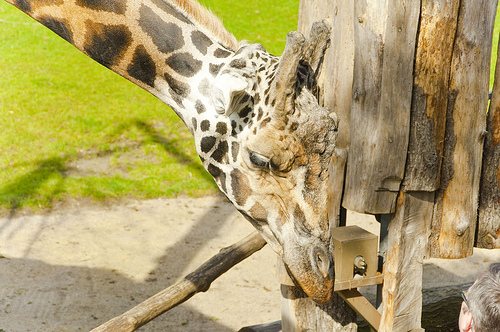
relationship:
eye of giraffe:
[253, 158, 290, 184] [185, 22, 337, 304]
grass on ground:
[13, 73, 86, 111] [265, 13, 287, 20]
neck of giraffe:
[88, 24, 221, 88] [185, 22, 337, 304]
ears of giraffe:
[261, 24, 351, 116] [185, 22, 337, 304]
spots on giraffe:
[195, 137, 223, 165] [185, 22, 337, 304]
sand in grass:
[60, 223, 133, 247] [13, 73, 86, 111]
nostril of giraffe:
[311, 246, 336, 282] [185, 22, 337, 304]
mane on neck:
[159, 3, 236, 47] [88, 24, 221, 88]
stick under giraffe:
[138, 256, 263, 307] [185, 22, 337, 304]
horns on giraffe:
[256, 24, 307, 111] [185, 22, 337, 304]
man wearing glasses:
[445, 258, 484, 331] [453, 287, 483, 311]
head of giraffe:
[166, 42, 347, 309] [185, 22, 337, 304]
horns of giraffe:
[256, 24, 307, 111] [185, 22, 337, 304]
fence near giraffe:
[396, 172, 490, 231] [185, 22, 337, 304]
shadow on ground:
[19, 268, 110, 289] [265, 13, 287, 20]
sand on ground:
[60, 223, 133, 247] [265, 13, 287, 20]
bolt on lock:
[346, 258, 382, 273] [326, 237, 380, 289]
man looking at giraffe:
[445, 258, 484, 331] [185, 22, 337, 304]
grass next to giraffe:
[13, 73, 86, 111] [185, 22, 337, 304]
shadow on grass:
[19, 268, 110, 289] [13, 73, 86, 111]